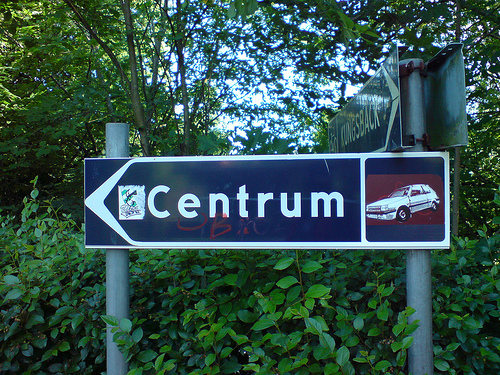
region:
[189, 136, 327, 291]
a sign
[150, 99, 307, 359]
a sign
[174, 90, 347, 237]
a sign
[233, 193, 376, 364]
a sign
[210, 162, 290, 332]
a sign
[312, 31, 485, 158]
the sign says Kingsback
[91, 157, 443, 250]
this sign points to Centrum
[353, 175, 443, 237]
the car is white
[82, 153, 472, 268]
the sign is blue & white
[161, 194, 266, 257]
it has red grafitti on the sign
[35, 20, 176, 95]
the trees are lush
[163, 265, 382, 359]
the bushes are very thick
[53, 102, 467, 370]
the sign is on metal posts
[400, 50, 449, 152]
the bolts appear to be rusted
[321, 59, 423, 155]
this sign is blue & white as well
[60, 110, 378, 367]
picture taken outdoors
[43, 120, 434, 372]
picture taken during theday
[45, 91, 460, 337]
the sun is out in the sky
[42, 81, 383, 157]
the sky is shining through the leaves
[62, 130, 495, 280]
a road sign says Centrum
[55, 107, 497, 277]
a picture of a car on the sign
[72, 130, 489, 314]
the sign is blue and white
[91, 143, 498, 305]
the car has red around it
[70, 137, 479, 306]
the sign is on two poles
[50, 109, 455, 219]
another sign is perpendicular to the sign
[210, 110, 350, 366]
a sign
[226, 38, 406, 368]
a sign